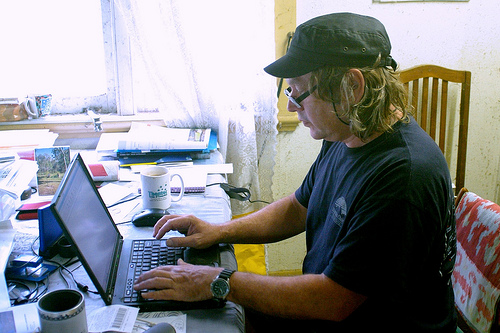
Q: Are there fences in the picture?
A: No, there are no fences.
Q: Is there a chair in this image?
A: Yes, there is a chair.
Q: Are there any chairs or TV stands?
A: Yes, there is a chair.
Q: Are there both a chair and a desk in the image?
A: Yes, there are both a chair and a desk.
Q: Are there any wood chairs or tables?
A: Yes, there is a wood chair.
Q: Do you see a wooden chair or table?
A: Yes, there is a wood chair.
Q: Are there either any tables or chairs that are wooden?
A: Yes, the chair is wooden.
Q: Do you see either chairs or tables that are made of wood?
A: Yes, the chair is made of wood.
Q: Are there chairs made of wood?
A: Yes, there is a chair that is made of wood.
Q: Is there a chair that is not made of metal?
A: Yes, there is a chair that is made of wood.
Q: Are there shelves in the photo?
A: No, there are no shelves.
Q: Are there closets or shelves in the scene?
A: No, there are no shelves or closets.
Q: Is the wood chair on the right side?
A: Yes, the chair is on the right of the image.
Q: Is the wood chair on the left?
A: No, the chair is on the right of the image.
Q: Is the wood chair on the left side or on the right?
A: The chair is on the right of the image.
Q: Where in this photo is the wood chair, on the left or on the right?
A: The chair is on the right of the image.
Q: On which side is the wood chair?
A: The chair is on the right of the image.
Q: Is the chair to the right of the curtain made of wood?
A: Yes, the chair is made of wood.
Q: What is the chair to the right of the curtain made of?
A: The chair is made of wood.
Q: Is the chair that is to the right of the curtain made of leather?
A: No, the chair is made of wood.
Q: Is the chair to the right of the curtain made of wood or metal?
A: The chair is made of wood.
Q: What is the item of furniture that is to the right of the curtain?
A: The piece of furniture is a chair.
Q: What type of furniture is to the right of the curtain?
A: The piece of furniture is a chair.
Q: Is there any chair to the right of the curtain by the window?
A: Yes, there is a chair to the right of the curtain.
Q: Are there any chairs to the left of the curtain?
A: No, the chair is to the right of the curtain.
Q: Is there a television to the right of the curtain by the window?
A: No, there is a chair to the right of the curtain.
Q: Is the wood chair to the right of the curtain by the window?
A: Yes, the chair is to the right of the curtain.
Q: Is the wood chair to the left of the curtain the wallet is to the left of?
A: No, the chair is to the right of the curtain.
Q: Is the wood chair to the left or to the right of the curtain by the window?
A: The chair is to the right of the curtain.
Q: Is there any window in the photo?
A: Yes, there is a window.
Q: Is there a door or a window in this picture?
A: Yes, there is a window.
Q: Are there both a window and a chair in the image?
A: Yes, there are both a window and a chair.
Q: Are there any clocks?
A: No, there are no clocks.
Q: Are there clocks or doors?
A: No, there are no clocks or doors.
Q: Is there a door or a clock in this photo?
A: No, there are no clocks or doors.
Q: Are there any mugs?
A: Yes, there is a mug.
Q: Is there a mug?
A: Yes, there is a mug.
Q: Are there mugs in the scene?
A: Yes, there is a mug.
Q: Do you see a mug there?
A: Yes, there is a mug.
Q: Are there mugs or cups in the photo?
A: Yes, there is a mug.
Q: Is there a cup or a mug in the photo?
A: Yes, there is a mug.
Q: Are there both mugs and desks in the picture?
A: Yes, there are both a mug and a desk.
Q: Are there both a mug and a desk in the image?
A: Yes, there are both a mug and a desk.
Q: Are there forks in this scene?
A: No, there are no forks.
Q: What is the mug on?
A: The mug is on the desk.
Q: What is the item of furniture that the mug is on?
A: The piece of furniture is a desk.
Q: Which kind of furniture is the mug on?
A: The mug is on the desk.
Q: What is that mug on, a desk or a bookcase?
A: The mug is on a desk.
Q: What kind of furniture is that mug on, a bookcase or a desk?
A: The mug is on a desk.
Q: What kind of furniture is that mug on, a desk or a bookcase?
A: The mug is on a desk.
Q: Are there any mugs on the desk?
A: Yes, there is a mug on the desk.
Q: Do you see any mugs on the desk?
A: Yes, there is a mug on the desk.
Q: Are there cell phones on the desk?
A: No, there is a mug on the desk.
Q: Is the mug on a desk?
A: Yes, the mug is on a desk.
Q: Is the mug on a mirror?
A: No, the mug is on a desk.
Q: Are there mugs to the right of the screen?
A: Yes, there is a mug to the right of the screen.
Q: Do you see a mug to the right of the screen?
A: Yes, there is a mug to the right of the screen.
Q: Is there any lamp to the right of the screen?
A: No, there is a mug to the right of the screen.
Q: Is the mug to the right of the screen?
A: Yes, the mug is to the right of the screen.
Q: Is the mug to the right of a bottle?
A: No, the mug is to the right of the screen.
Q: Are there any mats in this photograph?
A: No, there are no mats.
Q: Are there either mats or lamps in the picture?
A: No, there are no mats or lamps.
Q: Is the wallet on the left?
A: Yes, the wallet is on the left of the image.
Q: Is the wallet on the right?
A: No, the wallet is on the left of the image.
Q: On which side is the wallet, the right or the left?
A: The wallet is on the left of the image.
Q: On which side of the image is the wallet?
A: The wallet is on the left of the image.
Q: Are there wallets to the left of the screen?
A: Yes, there is a wallet to the left of the screen.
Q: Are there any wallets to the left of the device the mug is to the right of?
A: Yes, there is a wallet to the left of the screen.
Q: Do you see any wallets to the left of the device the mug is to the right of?
A: Yes, there is a wallet to the left of the screen.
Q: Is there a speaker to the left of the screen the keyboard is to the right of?
A: No, there is a wallet to the left of the screen.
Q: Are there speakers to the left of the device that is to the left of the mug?
A: No, there is a wallet to the left of the screen.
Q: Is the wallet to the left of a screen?
A: Yes, the wallet is to the left of a screen.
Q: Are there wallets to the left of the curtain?
A: Yes, there is a wallet to the left of the curtain.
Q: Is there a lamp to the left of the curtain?
A: No, there is a wallet to the left of the curtain.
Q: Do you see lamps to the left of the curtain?
A: No, there is a wallet to the left of the curtain.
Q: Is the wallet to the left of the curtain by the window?
A: Yes, the wallet is to the left of the curtain.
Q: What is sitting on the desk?
A: The wallet is sitting on the desk.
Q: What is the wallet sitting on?
A: The wallet is sitting on the desk.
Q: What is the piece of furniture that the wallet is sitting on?
A: The piece of furniture is a desk.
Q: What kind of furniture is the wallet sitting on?
A: The wallet is sitting on the desk.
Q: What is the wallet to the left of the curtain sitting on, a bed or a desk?
A: The wallet is sitting on a desk.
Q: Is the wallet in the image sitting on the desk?
A: Yes, the wallet is sitting on the desk.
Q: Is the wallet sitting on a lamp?
A: No, the wallet is sitting on the desk.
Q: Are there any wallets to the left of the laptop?
A: Yes, there is a wallet to the left of the laptop.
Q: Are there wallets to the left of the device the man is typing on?
A: Yes, there is a wallet to the left of the laptop.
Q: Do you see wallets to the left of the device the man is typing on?
A: Yes, there is a wallet to the left of the laptop.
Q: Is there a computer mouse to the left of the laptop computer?
A: No, there is a wallet to the left of the laptop computer.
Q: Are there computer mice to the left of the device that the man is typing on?
A: No, there is a wallet to the left of the laptop computer.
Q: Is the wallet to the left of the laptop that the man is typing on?
A: Yes, the wallet is to the left of the laptop computer.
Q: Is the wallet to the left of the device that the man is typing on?
A: Yes, the wallet is to the left of the laptop computer.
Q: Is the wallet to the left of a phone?
A: No, the wallet is to the left of the laptop computer.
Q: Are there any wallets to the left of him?
A: Yes, there is a wallet to the left of the man.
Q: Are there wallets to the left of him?
A: Yes, there is a wallet to the left of the man.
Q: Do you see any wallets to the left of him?
A: Yes, there is a wallet to the left of the man.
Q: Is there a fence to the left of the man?
A: No, there is a wallet to the left of the man.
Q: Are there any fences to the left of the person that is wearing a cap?
A: No, there is a wallet to the left of the man.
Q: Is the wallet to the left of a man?
A: Yes, the wallet is to the left of a man.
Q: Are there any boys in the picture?
A: No, there are no boys.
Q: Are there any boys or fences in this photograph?
A: No, there are no boys or fences.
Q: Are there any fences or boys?
A: No, there are no boys or fences.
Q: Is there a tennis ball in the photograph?
A: No, there are no tennis balls.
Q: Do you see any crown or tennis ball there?
A: No, there are no tennis balls or crowns.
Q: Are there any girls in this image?
A: No, there are no girls.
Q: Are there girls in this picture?
A: No, there are no girls.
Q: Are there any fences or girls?
A: No, there are no girls or fences.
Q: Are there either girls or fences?
A: No, there are no girls or fences.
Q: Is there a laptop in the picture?
A: Yes, there is a laptop.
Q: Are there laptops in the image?
A: Yes, there is a laptop.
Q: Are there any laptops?
A: Yes, there is a laptop.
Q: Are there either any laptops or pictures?
A: Yes, there is a laptop.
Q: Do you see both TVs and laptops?
A: No, there is a laptop but no televisions.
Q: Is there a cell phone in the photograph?
A: No, there are no cell phones.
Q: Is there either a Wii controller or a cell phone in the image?
A: No, there are no cell phones or Wii controllers.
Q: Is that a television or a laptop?
A: That is a laptop.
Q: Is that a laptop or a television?
A: That is a laptop.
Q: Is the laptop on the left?
A: Yes, the laptop is on the left of the image.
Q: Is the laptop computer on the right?
A: No, the laptop computer is on the left of the image.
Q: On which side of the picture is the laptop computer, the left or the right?
A: The laptop computer is on the left of the image.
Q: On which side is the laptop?
A: The laptop is on the left of the image.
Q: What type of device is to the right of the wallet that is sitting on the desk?
A: The device is a laptop.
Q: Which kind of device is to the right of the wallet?
A: The device is a laptop.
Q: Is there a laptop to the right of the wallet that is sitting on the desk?
A: Yes, there is a laptop to the right of the wallet.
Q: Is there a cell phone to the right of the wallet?
A: No, there is a laptop to the right of the wallet.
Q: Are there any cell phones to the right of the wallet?
A: No, there is a laptop to the right of the wallet.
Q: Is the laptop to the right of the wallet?
A: Yes, the laptop is to the right of the wallet.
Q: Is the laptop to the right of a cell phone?
A: No, the laptop is to the right of the wallet.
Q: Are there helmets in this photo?
A: No, there are no helmets.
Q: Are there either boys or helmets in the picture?
A: No, there are no helmets or boys.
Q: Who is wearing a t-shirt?
A: The man is wearing a t-shirt.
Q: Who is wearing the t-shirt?
A: The man is wearing a t-shirt.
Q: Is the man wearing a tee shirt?
A: Yes, the man is wearing a tee shirt.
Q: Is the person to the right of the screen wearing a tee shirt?
A: Yes, the man is wearing a tee shirt.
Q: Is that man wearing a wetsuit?
A: No, the man is wearing a tee shirt.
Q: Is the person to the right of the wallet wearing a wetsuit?
A: No, the man is wearing a tee shirt.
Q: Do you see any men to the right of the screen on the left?
A: Yes, there is a man to the right of the screen.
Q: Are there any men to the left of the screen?
A: No, the man is to the right of the screen.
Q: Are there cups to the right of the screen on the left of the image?
A: No, there is a man to the right of the screen.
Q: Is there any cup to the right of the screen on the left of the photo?
A: No, there is a man to the right of the screen.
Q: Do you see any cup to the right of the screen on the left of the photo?
A: No, there is a man to the right of the screen.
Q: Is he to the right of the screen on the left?
A: Yes, the man is to the right of the screen.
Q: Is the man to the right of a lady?
A: No, the man is to the right of the screen.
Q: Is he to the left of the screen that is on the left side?
A: No, the man is to the right of the screen.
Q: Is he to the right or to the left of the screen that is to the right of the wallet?
A: The man is to the right of the screen.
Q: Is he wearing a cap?
A: Yes, the man is wearing a cap.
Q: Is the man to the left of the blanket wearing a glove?
A: No, the man is wearing a cap.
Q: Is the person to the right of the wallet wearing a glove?
A: No, the man is wearing a cap.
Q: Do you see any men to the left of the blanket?
A: Yes, there is a man to the left of the blanket.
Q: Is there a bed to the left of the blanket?
A: No, there is a man to the left of the blanket.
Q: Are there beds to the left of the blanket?
A: No, there is a man to the left of the blanket.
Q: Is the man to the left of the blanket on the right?
A: Yes, the man is to the left of the blanket.